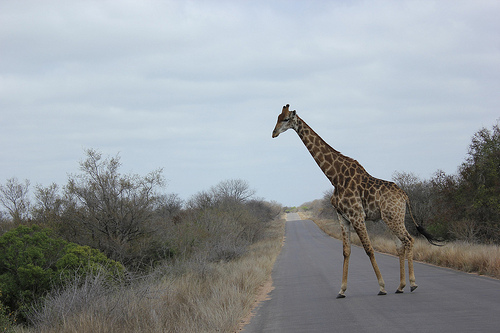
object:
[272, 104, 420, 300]
giraffe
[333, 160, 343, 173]
brown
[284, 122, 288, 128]
white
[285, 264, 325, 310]
grey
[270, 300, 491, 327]
ground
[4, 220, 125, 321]
bush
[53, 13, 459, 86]
sky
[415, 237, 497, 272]
grass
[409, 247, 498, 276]
side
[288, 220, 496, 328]
road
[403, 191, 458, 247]
tail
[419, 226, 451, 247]
hair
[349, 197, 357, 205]
spot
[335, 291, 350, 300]
hoof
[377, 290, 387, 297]
hoof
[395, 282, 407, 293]
hoof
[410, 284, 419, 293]
hoof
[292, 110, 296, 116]
ear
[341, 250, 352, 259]
knee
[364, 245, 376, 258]
knee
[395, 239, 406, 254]
knee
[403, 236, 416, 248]
knee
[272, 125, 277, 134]
nose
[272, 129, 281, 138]
mouth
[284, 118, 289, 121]
eye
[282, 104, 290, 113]
horns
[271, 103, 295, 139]
head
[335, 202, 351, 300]
leg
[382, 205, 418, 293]
leg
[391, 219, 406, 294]
leg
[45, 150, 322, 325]
wilderness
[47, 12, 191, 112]
clouds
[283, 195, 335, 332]
long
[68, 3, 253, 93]
overcast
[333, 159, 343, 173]
markings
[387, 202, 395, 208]
beige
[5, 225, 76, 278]
green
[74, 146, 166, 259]
tree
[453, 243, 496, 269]
brown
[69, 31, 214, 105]
cloudy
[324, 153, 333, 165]
spots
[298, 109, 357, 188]
long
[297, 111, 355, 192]
neck